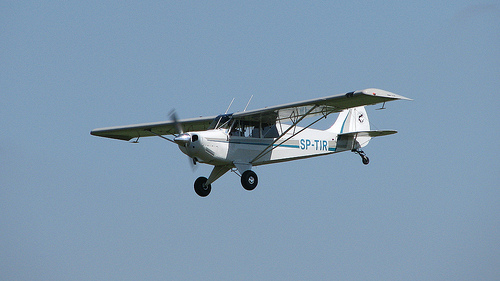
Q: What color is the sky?
A: Blue.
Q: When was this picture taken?
A: The daytime.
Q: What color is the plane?
A: White.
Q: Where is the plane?
A: In the sky.